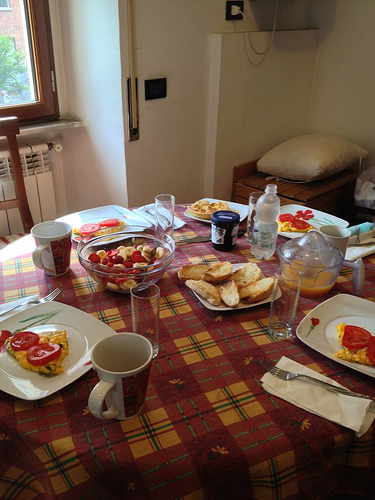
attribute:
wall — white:
[172, 38, 215, 116]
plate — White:
[2, 297, 120, 423]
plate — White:
[180, 257, 278, 311]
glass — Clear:
[105, 274, 178, 331]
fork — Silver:
[261, 360, 356, 391]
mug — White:
[86, 321, 152, 422]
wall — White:
[170, 76, 280, 134]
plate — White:
[2, 299, 117, 408]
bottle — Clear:
[251, 183, 281, 257]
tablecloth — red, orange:
[175, 322, 235, 391]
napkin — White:
[261, 351, 374, 437]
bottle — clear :
[249, 182, 279, 261]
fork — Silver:
[258, 356, 370, 399]